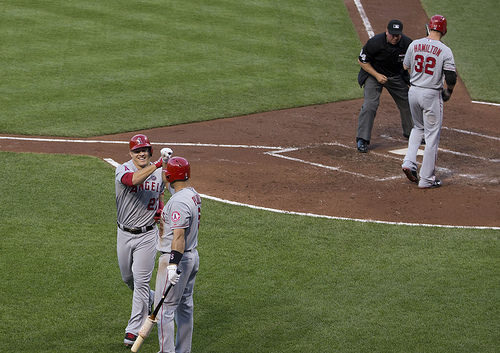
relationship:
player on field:
[114, 132, 166, 342] [4, 3, 495, 349]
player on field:
[154, 156, 204, 351] [4, 3, 495, 349]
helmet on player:
[127, 129, 153, 156] [114, 132, 166, 342]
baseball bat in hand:
[116, 266, 182, 353] [168, 264, 183, 284]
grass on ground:
[227, 228, 423, 328] [0, 0, 497, 348]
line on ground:
[205, 140, 296, 154] [0, 0, 497, 348]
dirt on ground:
[208, 159, 318, 202] [0, 0, 497, 348]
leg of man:
[420, 91, 444, 187] [400, 11, 460, 189]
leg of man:
[403, 88, 422, 187] [400, 11, 460, 189]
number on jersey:
[410, 50, 439, 82] [404, 37, 456, 87]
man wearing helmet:
[149, 156, 208, 352] [163, 154, 189, 181]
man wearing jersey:
[149, 156, 208, 352] [157, 185, 200, 251]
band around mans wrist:
[169, 249, 181, 262] [163, 243, 189, 273]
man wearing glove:
[149, 156, 208, 352] [167, 264, 180, 283]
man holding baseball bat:
[149, 156, 208, 352] [127, 270, 179, 350]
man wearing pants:
[149, 156, 208, 352] [157, 249, 200, 351]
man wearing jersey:
[112, 132, 162, 346] [115, 159, 166, 229]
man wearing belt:
[112, 132, 162, 346] [111, 220, 158, 233]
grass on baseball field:
[271, 234, 491, 331] [2, 0, 499, 347]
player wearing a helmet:
[154, 156, 204, 351] [164, 153, 190, 178]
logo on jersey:
[139, 177, 168, 195] [106, 163, 162, 228]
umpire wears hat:
[353, 20, 425, 151] [384, 15, 407, 45]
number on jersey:
[410, 50, 439, 75] [397, 34, 464, 94]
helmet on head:
[124, 134, 147, 155] [121, 130, 161, 173]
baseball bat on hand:
[116, 266, 182, 353] [168, 264, 184, 285]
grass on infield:
[0, 151, 499, 352] [0, 0, 369, 140]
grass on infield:
[86, 19, 200, 93] [50, 10, 217, 106]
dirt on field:
[273, 172, 309, 201] [206, 143, 382, 308]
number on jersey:
[410, 50, 439, 82] [395, 35, 458, 87]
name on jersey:
[408, 34, 448, 63] [401, 35, 459, 93]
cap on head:
[386, 17, 409, 38] [375, 19, 407, 46]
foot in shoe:
[346, 139, 364, 162] [341, 132, 368, 159]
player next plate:
[388, 6, 460, 200] [386, 137, 426, 160]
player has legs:
[388, 6, 460, 200] [395, 106, 449, 191]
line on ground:
[205, 140, 296, 154] [182, 75, 351, 171]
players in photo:
[104, 121, 209, 351] [6, 3, 498, 348]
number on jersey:
[410, 50, 439, 82] [401, 35, 459, 93]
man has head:
[346, 12, 407, 157] [375, 12, 413, 53]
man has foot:
[346, 12, 407, 157] [344, 128, 371, 155]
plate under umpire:
[386, 137, 426, 160] [353, 20, 425, 151]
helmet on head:
[127, 129, 153, 156] [127, 134, 154, 161]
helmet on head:
[428, 11, 447, 32] [425, 9, 450, 39]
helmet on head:
[162, 155, 192, 180] [165, 153, 191, 188]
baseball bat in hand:
[116, 266, 182, 353] [163, 260, 186, 286]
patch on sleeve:
[168, 205, 183, 223] [160, 197, 190, 231]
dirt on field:
[0, 6, 500, 226] [4, 3, 495, 349]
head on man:
[129, 131, 153, 165] [112, 132, 162, 346]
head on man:
[163, 153, 193, 185] [149, 156, 203, 348]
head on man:
[425, 11, 450, 41] [401, 13, 466, 188]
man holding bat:
[149, 156, 203, 348] [127, 262, 180, 346]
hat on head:
[383, 17, 406, 43] [384, 20, 405, 46]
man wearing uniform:
[112, 132, 162, 346] [154, 182, 202, 351]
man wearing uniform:
[149, 156, 203, 348] [402, 33, 458, 180]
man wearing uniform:
[400, 11, 460, 189] [357, 30, 414, 140]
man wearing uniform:
[346, 12, 407, 157] [357, 30, 414, 140]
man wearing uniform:
[112, 132, 162, 346] [115, 164, 166, 330]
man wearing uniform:
[400, 11, 460, 189] [401, 38, 455, 187]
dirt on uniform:
[156, 211, 161, 237] [155, 187, 197, 350]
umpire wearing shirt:
[353, 20, 425, 151] [361, 33, 409, 78]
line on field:
[196, 189, 498, 229] [4, 3, 495, 349]